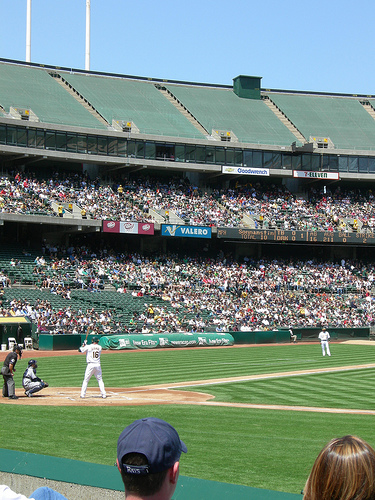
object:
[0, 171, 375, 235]
people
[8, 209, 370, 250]
stand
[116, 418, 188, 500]
person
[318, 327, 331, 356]
player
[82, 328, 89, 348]
bat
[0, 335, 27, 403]
umpire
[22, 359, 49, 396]
catcher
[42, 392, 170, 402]
home plate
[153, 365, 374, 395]
lines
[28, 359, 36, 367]
helmet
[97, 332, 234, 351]
advertisement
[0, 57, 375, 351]
baseball stadium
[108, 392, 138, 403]
markings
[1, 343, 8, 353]
players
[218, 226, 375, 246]
game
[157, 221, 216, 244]
sign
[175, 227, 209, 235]
valero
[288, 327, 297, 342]
man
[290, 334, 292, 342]
chair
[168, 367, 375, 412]
pattern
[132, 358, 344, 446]
grass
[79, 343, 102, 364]
jersey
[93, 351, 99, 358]
16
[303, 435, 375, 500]
woman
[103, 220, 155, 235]
dr pepper banner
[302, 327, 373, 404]
team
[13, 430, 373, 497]
spectators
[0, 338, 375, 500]
foreground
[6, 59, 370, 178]
skybox seats